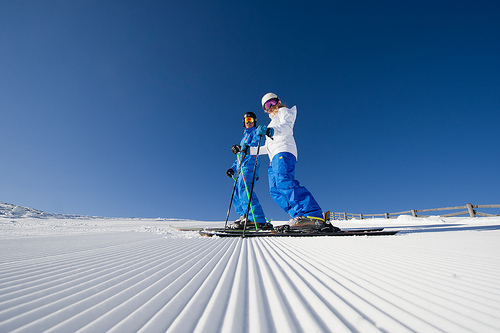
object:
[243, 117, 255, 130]
face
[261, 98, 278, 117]
face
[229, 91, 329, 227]
person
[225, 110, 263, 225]
man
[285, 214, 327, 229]
shoe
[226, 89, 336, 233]
man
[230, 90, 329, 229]
man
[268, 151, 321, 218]
pants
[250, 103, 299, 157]
shirt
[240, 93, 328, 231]
man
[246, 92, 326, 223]
man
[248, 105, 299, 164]
jacket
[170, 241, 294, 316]
snow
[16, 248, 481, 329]
ground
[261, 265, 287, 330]
line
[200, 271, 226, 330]
line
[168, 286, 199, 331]
line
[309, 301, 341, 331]
line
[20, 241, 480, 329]
snow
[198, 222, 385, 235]
skating machine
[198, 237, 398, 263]
ice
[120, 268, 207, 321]
snow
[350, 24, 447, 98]
sky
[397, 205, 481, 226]
fence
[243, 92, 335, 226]
woman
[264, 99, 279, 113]
goggles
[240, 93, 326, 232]
woman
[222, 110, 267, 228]
man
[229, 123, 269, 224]
suit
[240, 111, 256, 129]
helmet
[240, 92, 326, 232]
person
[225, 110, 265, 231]
person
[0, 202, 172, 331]
mountain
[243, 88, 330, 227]
person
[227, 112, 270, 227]
person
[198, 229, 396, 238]
skis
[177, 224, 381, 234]
skis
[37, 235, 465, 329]
ground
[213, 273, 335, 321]
snow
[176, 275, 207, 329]
line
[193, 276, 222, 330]
line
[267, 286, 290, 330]
line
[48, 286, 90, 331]
line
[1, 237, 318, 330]
ground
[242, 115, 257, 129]
goggles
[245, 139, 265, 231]
pole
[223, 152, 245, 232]
pole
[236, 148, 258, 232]
pole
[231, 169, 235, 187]
pole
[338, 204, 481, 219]
fence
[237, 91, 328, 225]
woman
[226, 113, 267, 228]
woman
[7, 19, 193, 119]
ski